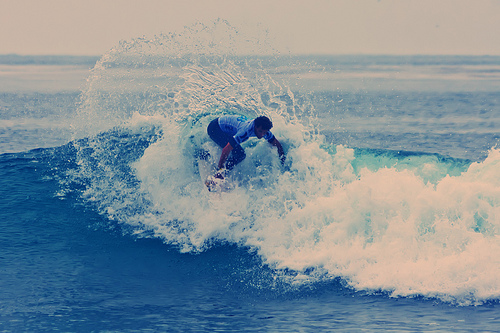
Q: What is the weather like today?
A: It is clear.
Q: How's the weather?
A: It is clear.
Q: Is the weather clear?
A: Yes, it is clear.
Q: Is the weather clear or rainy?
A: It is clear.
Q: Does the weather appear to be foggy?
A: No, it is clear.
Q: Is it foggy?
A: No, it is clear.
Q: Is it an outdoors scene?
A: Yes, it is outdoors.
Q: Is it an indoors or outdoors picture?
A: It is outdoors.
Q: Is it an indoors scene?
A: No, it is outdoors.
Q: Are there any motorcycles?
A: No, there are no motorcycles.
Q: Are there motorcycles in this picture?
A: No, there are no motorcycles.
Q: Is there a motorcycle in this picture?
A: No, there are no motorcycles.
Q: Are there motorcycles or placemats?
A: No, there are no motorcycles or placemats.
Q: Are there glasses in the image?
A: No, there are no glasses.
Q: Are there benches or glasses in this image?
A: No, there are no glasses or benches.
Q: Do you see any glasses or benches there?
A: No, there are no glasses or benches.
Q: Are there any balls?
A: No, there are no balls.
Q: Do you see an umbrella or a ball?
A: No, there are no balls or umbrellas.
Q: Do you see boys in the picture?
A: No, there are no boys.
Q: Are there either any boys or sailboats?
A: No, there are no boys or sailboats.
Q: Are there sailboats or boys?
A: No, there are no boys or sailboats.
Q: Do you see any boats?
A: No, there are no boats.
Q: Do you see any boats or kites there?
A: No, there are no boats or kites.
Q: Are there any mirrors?
A: No, there are no mirrors.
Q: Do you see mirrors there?
A: No, there are no mirrors.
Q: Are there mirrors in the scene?
A: No, there are no mirrors.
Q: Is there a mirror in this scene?
A: No, there are no mirrors.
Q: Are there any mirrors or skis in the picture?
A: No, there are no mirrors or skis.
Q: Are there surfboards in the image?
A: Yes, there is a surfboard.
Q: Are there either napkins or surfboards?
A: Yes, there is a surfboard.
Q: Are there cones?
A: No, there are no cones.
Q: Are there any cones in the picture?
A: No, there are no cones.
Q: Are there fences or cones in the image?
A: No, there are no cones or fences.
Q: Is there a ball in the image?
A: No, there are no balls.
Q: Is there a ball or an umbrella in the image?
A: No, there are no balls or umbrellas.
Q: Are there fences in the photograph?
A: No, there are no fences.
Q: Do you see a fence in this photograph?
A: No, there are no fences.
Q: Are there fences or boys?
A: No, there are no fences or boys.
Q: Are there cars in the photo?
A: No, there are no cars.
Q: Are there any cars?
A: No, there are no cars.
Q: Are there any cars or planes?
A: No, there are no cars or planes.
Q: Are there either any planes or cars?
A: No, there are no cars or planes.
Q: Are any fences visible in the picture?
A: No, there are no fences.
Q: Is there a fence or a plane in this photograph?
A: No, there are no fences or airplanes.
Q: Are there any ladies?
A: No, there are no ladies.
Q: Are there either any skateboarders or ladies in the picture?
A: No, there are no ladies or skateboarders.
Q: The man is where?
A: The man is in the ocean.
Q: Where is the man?
A: The man is in the ocean.